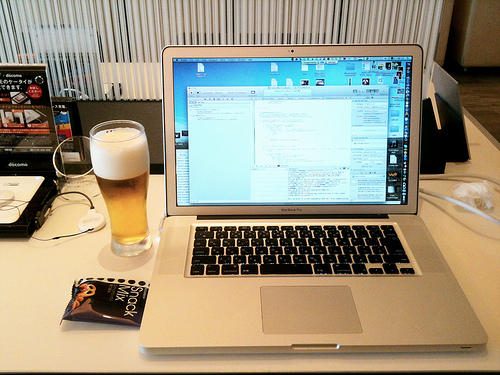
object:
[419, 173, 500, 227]
cable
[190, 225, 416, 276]
keyboard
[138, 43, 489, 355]
laptop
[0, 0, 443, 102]
shutters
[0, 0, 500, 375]
computer's room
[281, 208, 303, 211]
letters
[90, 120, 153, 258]
beer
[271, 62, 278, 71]
icon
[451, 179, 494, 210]
tissue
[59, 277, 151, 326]
snack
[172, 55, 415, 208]
laptop screen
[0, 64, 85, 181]
magazines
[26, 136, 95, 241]
cords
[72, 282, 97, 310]
image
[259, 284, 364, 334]
trackpad